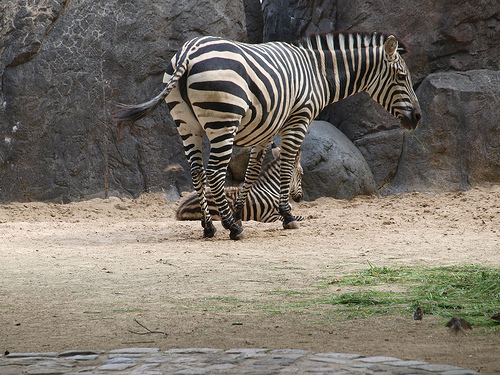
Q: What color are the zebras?
A: Black and white.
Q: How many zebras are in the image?
A: Two.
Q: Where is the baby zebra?
A: Behind the adult zebra.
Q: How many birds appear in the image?
A: Two.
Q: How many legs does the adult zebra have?
A: Four.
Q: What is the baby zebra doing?
A: Laying on the ground.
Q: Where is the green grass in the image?
A: On the right lower side.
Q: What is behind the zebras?
A: A rock wall.